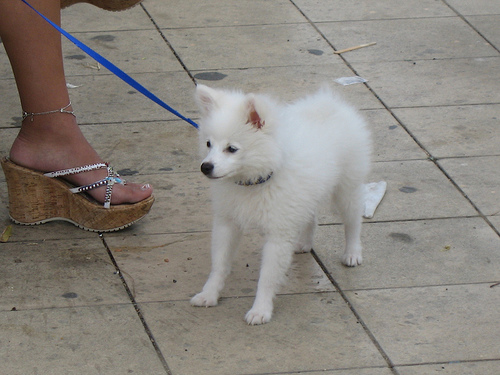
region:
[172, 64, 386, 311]
the puppy is white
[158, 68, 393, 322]
the puppy is white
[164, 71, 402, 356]
the puppy is white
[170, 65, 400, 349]
the puppy is white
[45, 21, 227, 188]
the leash is blue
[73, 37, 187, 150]
the leash is blue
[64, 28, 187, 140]
the leash is blue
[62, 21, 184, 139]
the leash is blue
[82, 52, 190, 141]
the leash is blue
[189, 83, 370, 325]
a small white dog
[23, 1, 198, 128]
a blue fabric leash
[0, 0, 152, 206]
a woman's foot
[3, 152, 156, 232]
a high heeled woman's sandal shoe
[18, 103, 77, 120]
a silver ankle bracelet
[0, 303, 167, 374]
a square pavement tile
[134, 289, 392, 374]
a square pavement tile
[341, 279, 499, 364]
a square pavement tile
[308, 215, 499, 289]
a square pavement tile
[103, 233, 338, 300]
a square pavement tile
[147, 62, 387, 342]
small white dog on leash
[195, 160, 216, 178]
small black nose on dog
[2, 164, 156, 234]
brown sandal on girl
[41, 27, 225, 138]
blue leash on dog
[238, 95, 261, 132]
pink inner ear of dog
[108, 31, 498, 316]
tile floor under dog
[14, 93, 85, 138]
anklet on woman's leg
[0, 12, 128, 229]
leg of woman walking dog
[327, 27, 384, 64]
old stick on ground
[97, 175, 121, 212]
black writing on shoe straps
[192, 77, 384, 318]
small white dog outside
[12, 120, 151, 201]
the woman's left foot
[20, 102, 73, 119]
bracelet on woman's ankle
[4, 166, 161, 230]
wedge on the woman's foot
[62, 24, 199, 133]
blue leash on the dog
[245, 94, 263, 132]
left ear on the dog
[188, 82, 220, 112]
right ear on the dog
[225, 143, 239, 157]
left eye on the dog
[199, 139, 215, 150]
right eye on the dog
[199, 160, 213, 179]
black nose on dog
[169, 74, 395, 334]
a small white dog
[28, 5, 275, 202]
blue leash to dog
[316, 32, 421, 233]
liter on the ground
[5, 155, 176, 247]
a platform type sandal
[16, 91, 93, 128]
an ankle bracelet on ankle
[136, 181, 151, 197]
toe nail on big toe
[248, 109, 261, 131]
pink inside dog's ear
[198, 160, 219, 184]
black nose on dog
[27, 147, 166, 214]
a multi colored sandal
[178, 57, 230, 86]
a black spot on the ground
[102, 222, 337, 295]
A tile in a floor.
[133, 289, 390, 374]
A tile in a floor.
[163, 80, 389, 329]
white dog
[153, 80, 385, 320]
small white dog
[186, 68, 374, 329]
small white dog on sidewalk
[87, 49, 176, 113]
blue leash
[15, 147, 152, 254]
shoe worn by woman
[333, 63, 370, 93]
paper on side walk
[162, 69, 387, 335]
white small dog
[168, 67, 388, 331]
white small dog on sidewalk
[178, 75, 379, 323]
white small dog being walked on sidewalk